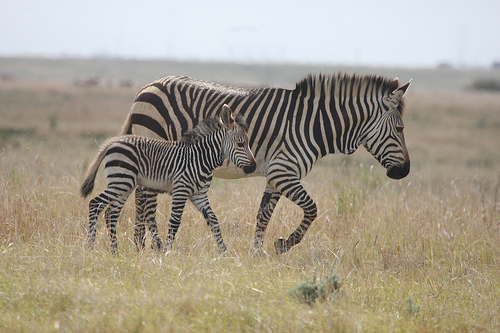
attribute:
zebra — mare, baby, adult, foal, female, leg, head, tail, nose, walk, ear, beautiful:
[66, 58, 411, 294]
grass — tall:
[408, 197, 458, 264]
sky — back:
[171, 16, 215, 49]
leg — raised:
[160, 171, 237, 248]